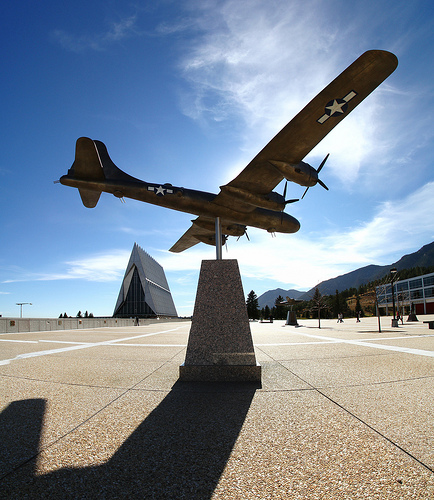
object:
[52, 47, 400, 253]
airplane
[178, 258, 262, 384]
pedestal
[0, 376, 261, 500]
shadow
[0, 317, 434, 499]
ground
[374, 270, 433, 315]
building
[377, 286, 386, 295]
window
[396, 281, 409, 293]
window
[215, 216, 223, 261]
pole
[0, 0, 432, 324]
sky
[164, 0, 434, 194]
cloud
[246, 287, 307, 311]
mountain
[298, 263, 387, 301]
mountain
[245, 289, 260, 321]
tree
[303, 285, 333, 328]
tree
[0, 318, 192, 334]
wall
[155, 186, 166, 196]
star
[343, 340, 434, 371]
line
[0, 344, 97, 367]
line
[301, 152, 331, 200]
propeller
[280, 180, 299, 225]
propeller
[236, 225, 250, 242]
propeller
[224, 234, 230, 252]
propeller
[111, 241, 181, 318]
building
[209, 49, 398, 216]
wing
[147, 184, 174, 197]
logo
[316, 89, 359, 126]
logo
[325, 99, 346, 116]
star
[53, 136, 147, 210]
tail